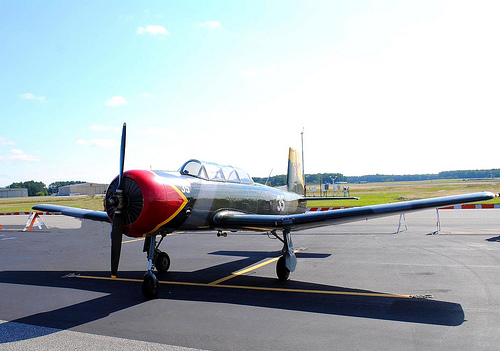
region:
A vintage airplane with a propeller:
[20, 93, 494, 314]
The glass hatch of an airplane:
[173, 150, 264, 198]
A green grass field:
[361, 187, 401, 204]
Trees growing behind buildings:
[3, 173, 100, 205]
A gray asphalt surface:
[352, 240, 474, 284]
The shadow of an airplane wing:
[314, 275, 478, 333]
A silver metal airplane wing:
[210, 179, 499, 241]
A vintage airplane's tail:
[275, 135, 320, 208]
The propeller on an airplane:
[76, 111, 159, 293]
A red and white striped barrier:
[456, 199, 498, 213]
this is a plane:
[67, 116, 442, 288]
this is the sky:
[8, 4, 127, 99]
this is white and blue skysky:
[40, 18, 450, 143]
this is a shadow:
[12, 260, 455, 349]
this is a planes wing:
[223, 185, 499, 268]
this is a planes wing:
[25, 189, 116, 249]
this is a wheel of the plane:
[267, 248, 316, 282]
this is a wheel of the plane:
[131, 269, 176, 298]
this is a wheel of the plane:
[148, 244, 188, 278]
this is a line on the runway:
[153, 265, 429, 319]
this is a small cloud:
[94, 73, 156, 138]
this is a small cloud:
[137, 13, 183, 58]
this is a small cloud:
[20, 82, 50, 118]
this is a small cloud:
[97, 88, 135, 123]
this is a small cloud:
[10, 150, 46, 186]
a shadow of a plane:
[314, 272, 432, 337]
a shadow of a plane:
[198, 264, 295, 316]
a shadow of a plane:
[41, 292, 130, 337]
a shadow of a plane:
[40, 232, 127, 289]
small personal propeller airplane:
[53, 146, 385, 293]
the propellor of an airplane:
[109, 113, 133, 290]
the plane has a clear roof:
[174, 157, 253, 193]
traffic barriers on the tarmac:
[7, 207, 45, 230]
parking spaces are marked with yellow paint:
[77, 257, 325, 313]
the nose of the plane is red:
[118, 175, 175, 230]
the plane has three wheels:
[132, 248, 300, 290]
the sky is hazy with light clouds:
[207, 81, 404, 132]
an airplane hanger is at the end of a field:
[50, 186, 100, 191]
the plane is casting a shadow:
[178, 283, 363, 320]